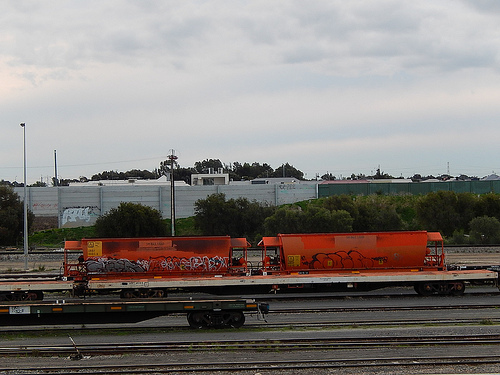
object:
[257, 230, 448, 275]
train car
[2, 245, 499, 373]
platform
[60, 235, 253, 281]
train car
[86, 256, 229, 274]
graffiti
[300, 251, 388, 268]
graffiti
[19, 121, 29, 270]
light post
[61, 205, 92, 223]
graffiti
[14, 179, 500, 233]
wall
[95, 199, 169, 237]
bush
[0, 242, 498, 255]
tracks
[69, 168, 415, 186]
building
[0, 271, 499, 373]
tracks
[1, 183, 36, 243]
tree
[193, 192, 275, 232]
tree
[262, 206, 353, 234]
tree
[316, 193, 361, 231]
tree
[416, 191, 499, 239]
tree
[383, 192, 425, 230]
tree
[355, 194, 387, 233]
tree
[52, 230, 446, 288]
train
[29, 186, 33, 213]
wall divider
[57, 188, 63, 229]
wall divider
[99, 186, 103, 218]
wall divider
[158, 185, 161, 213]
wall divider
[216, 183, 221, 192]
wall divider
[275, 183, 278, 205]
wall divider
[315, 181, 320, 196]
wall divider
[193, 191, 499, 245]
trees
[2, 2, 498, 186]
sky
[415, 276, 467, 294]
wheels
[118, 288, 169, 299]
wheels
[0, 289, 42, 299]
wheels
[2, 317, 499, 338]
grass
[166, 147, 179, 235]
power line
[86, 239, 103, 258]
sticker